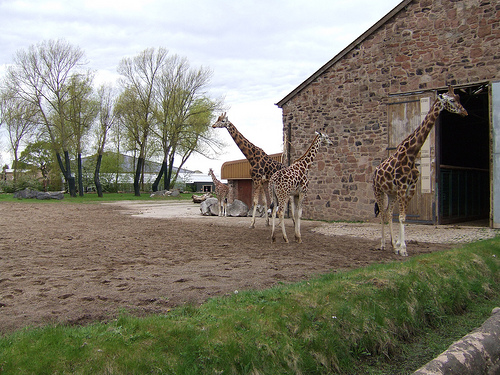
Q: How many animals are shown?
A: 4.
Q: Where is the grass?
A: On the right.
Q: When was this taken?
A: Daytime.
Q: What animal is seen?
A: Giraffes.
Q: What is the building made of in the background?
A: Stone.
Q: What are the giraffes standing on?
A: Dirt.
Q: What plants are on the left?
A: Trees.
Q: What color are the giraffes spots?
A: Brown.